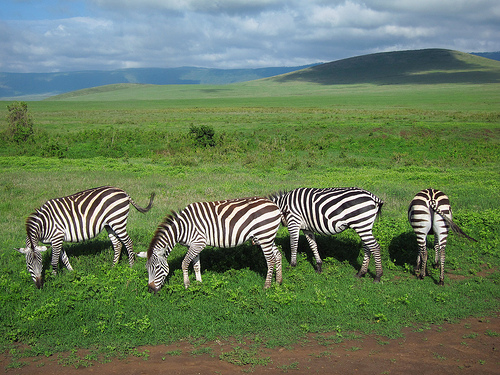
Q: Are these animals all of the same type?
A: Yes, all the animals are zebras.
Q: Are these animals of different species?
A: No, all the animals are zebras.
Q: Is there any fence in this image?
A: No, there are no fences.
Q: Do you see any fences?
A: No, there are no fences.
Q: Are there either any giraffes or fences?
A: No, there are no fences or giraffes.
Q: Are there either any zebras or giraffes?
A: Yes, there is a zebra.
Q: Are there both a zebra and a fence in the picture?
A: No, there is a zebra but no fences.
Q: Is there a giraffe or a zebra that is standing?
A: Yes, the zebra is standing.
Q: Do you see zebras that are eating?
A: Yes, there is a zebra that is eating.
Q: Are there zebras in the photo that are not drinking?
A: Yes, there is a zebra that is eating.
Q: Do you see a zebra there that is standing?
A: Yes, there is a zebra that is standing.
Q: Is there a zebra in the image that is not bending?
A: Yes, there is a zebra that is standing.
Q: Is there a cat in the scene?
A: No, there are no cats.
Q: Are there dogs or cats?
A: No, there are no cats or dogs.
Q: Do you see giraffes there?
A: No, there are no giraffes.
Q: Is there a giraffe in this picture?
A: No, there are no giraffes.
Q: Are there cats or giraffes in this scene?
A: No, there are no giraffes or cats.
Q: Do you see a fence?
A: No, there are no fences.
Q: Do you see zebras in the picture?
A: Yes, there is a zebra.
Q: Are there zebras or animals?
A: Yes, there is a zebra.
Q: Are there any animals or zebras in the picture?
A: Yes, there is a zebra.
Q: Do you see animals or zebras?
A: Yes, there is a zebra.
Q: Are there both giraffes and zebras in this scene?
A: No, there is a zebra but no giraffes.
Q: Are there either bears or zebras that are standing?
A: Yes, the zebra is standing.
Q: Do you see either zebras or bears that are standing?
A: Yes, the zebra is standing.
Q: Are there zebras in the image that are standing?
A: Yes, there is a zebra that is standing.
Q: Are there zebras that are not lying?
A: Yes, there is a zebra that is standing.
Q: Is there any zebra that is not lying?
A: Yes, there is a zebra that is standing.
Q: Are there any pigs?
A: No, there are no pigs.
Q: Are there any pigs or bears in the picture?
A: No, there are no pigs or bears.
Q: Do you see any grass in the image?
A: Yes, there is grass.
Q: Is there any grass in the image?
A: Yes, there is grass.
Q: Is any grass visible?
A: Yes, there is grass.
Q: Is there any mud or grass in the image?
A: Yes, there is grass.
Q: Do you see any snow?
A: No, there is no snow.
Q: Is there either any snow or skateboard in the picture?
A: No, there are no snow or skateboards.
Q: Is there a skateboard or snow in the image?
A: No, there are no snow or skateboards.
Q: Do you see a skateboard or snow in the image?
A: No, there are no snow or skateboards.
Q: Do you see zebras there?
A: Yes, there is a zebra.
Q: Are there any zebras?
A: Yes, there is a zebra.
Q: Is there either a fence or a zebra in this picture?
A: Yes, there is a zebra.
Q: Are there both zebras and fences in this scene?
A: No, there is a zebra but no fences.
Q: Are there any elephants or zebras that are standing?
A: Yes, the zebra is standing.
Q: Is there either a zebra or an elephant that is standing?
A: Yes, the zebra is standing.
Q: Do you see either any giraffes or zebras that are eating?
A: Yes, the zebra is eating.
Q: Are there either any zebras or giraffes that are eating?
A: Yes, the zebra is eating.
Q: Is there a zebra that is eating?
A: Yes, there is a zebra that is eating.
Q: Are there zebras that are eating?
A: Yes, there is a zebra that is eating.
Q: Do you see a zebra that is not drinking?
A: Yes, there is a zebra that is eating .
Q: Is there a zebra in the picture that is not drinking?
A: Yes, there is a zebra that is eating.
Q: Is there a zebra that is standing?
A: Yes, there is a zebra that is standing.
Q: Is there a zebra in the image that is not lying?
A: Yes, there is a zebra that is standing.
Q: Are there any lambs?
A: No, there are no lambs.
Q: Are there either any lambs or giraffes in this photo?
A: No, there are no lambs or giraffes.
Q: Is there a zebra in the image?
A: Yes, there is a zebra.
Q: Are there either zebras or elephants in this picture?
A: Yes, there is a zebra.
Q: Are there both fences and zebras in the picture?
A: No, there is a zebra but no fences.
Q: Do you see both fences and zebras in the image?
A: No, there is a zebra but no fences.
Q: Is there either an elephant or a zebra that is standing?
A: Yes, the zebra is standing.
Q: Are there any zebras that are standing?
A: Yes, there is a zebra that is standing.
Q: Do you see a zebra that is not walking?
A: Yes, there is a zebra that is standing .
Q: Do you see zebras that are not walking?
A: Yes, there is a zebra that is standing .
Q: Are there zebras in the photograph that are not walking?
A: Yes, there is a zebra that is standing.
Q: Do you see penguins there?
A: No, there are no penguins.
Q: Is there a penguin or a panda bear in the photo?
A: No, there are no penguins or pandas.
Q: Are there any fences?
A: No, there are no fences.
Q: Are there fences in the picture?
A: No, there are no fences.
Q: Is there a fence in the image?
A: No, there are no fences.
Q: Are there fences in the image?
A: No, there are no fences.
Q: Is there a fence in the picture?
A: No, there are no fences.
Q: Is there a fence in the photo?
A: No, there are no fences.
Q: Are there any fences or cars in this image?
A: No, there are no fences or cars.